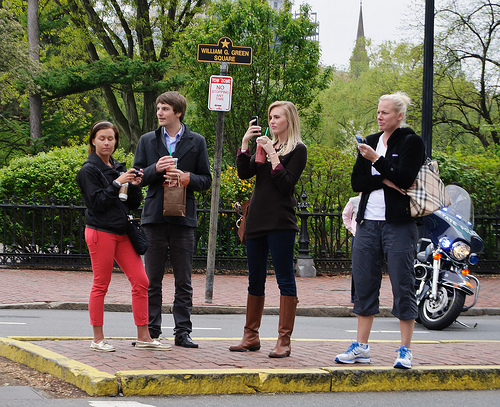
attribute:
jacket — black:
[132, 124, 211, 226]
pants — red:
[80, 222, 151, 332]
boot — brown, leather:
[269, 287, 301, 361]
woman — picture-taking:
[227, 100, 309, 357]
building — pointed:
[334, 0, 372, 79]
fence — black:
[6, 187, 498, 268]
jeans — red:
[58, 206, 168, 355]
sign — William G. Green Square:
[194, 37, 254, 67]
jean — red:
[86, 225, 147, 325]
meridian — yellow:
[1, 328, 483, 396]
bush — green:
[227, 137, 368, 266]